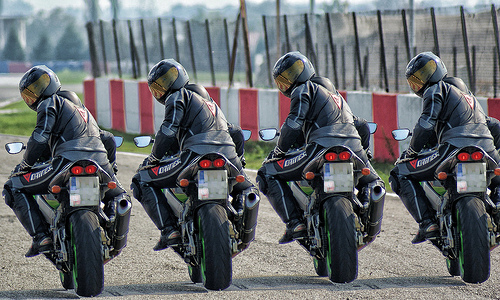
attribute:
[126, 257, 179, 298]
gravel — fine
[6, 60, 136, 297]
motorcycle rider — on left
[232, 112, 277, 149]
mirror — rear view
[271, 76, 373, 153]
jacket — black, leather, white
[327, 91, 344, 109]
logo — red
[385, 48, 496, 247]
rider — on right, quartet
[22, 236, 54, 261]
shoe — black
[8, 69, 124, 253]
riders — looking back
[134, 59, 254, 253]
riders — looking back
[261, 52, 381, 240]
riders — looking back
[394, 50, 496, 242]
riders — looking back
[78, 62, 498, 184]
tarp — striped, red, white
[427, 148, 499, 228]
plate — on right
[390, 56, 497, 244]
motorcyclist — grouped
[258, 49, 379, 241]
motorcyclist — grouped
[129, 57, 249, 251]
motorcyclist — grouped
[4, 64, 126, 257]
motorcyclist — grouped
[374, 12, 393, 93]
pole — wooden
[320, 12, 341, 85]
pole — wooden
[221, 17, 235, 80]
pole — wooden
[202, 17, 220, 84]
pole — wooden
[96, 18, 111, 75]
pole — wooden